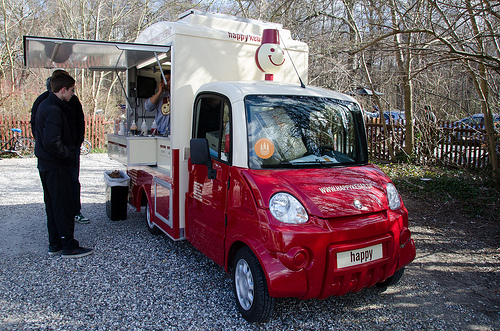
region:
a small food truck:
[114, 22, 414, 311]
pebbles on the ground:
[107, 263, 172, 310]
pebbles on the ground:
[132, 246, 227, 318]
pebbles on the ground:
[60, 255, 140, 320]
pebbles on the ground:
[64, 235, 179, 312]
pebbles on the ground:
[323, 290, 360, 324]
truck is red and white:
[88, 23, 423, 305]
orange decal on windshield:
[249, 122, 291, 169]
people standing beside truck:
[22, 65, 116, 271]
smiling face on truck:
[247, 15, 302, 81]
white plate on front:
[328, 236, 405, 276]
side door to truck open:
[1, 18, 172, 85]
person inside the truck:
[126, 70, 179, 137]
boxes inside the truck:
[209, 90, 309, 167]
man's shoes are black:
[48, 230, 99, 262]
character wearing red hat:
[256, 11, 283, 53]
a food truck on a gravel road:
[21, 10, 418, 315]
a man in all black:
[30, 74, 92, 259]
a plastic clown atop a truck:
[254, 25, 286, 78]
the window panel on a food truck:
[21, 34, 166, 69]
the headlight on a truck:
[272, 188, 295, 219]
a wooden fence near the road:
[367, 115, 498, 170]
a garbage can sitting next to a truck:
[101, 165, 128, 218]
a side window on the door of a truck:
[190, 138, 216, 177]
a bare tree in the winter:
[305, 0, 418, 161]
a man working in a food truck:
[144, 72, 171, 133]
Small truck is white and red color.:
[87, 22, 357, 257]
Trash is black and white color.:
[96, 169, 128, 224]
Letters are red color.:
[333, 230, 405, 278]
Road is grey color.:
[21, 242, 182, 316]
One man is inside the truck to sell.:
[128, 67, 196, 153]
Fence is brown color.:
[4, 107, 122, 164]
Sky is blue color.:
[26, 9, 427, 34]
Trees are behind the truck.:
[21, 25, 496, 148]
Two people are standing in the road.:
[22, 69, 114, 272]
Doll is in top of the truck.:
[250, 19, 302, 91]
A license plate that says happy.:
[326, 227, 390, 278]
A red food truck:
[8, 8, 435, 322]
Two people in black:
[23, 66, 105, 262]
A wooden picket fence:
[367, 115, 491, 167]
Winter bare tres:
[305, 0, 493, 105]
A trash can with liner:
[101, 166, 132, 227]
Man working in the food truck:
[140, 68, 171, 137]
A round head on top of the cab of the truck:
[243, 20, 292, 78]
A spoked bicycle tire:
[11, 131, 41, 165]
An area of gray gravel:
[5, 228, 205, 327]